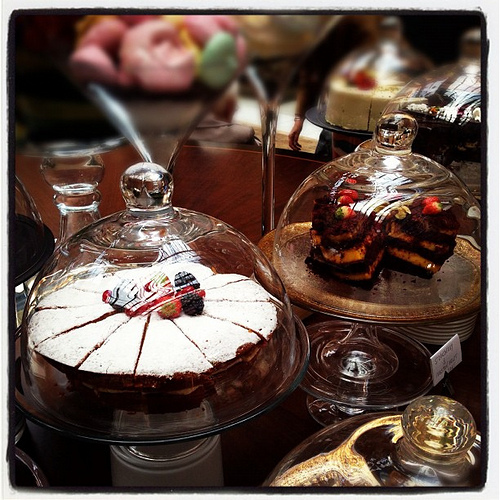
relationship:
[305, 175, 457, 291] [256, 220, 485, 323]
cake sitting on platter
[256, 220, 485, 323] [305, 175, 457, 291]
platter for cake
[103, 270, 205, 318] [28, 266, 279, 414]
fruit on top of cake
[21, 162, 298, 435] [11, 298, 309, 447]
lid on top of platter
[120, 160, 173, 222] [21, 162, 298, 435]
handle for lid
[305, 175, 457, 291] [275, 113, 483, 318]
cake under lid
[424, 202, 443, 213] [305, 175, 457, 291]
strawberry on top of cake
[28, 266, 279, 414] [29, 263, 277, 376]
cake has frosting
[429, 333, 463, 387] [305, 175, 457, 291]
sign for cake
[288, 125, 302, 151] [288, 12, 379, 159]
hand of person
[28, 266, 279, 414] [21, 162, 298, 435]
cake under lid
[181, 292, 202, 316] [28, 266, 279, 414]
berry on top of cake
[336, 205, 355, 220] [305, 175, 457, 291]
strawberry on top of cake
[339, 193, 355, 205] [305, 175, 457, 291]
strawberry on top of cake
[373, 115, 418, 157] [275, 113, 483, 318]
knob on top of lid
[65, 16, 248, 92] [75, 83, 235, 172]
dessert sitting in cup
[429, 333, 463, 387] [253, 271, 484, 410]
sign attached to cake stand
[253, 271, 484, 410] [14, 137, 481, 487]
cake stand placed on table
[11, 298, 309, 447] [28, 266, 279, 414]
platter with cake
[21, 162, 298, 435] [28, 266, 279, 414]
lid with cake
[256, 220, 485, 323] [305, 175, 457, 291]
platter with cake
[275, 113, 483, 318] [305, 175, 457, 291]
lid with cake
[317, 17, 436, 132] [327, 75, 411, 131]
container with pastry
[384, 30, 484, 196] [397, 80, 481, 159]
container with pastry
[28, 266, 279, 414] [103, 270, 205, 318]
cake with fruit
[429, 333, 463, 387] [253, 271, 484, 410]
sign in front of cake stand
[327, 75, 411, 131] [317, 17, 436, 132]
pastry displayed in container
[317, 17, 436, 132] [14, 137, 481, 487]
container sitting on table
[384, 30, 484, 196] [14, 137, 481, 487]
container sitting on table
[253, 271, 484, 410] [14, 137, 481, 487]
cake stand sitting on table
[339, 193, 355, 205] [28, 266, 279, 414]
strawberry on top of cake